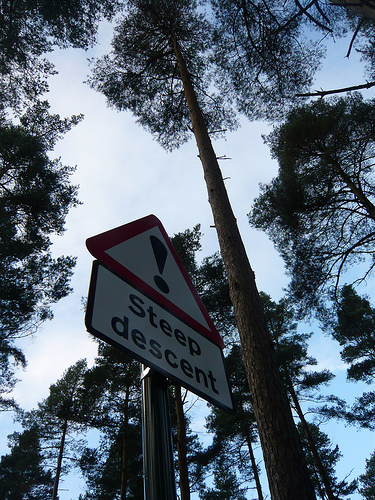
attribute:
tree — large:
[82, 0, 332, 154]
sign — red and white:
[85, 212, 224, 343]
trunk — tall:
[176, 77, 324, 498]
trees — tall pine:
[91, 1, 335, 497]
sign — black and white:
[80, 212, 264, 415]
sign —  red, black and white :
[93, 202, 270, 392]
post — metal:
[142, 365, 172, 494]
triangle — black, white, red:
[83, 211, 223, 349]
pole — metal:
[139, 375, 185, 498]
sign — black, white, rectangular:
[63, 187, 209, 386]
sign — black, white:
[64, 195, 246, 413]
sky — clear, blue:
[83, 139, 170, 209]